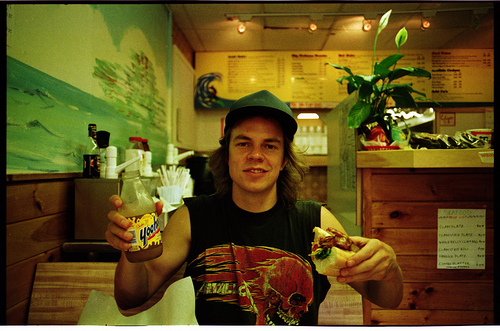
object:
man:
[104, 89, 403, 326]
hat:
[223, 89, 298, 142]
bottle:
[117, 170, 164, 263]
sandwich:
[307, 225, 362, 277]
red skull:
[263, 256, 313, 326]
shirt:
[181, 193, 331, 325]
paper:
[437, 208, 486, 269]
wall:
[361, 168, 493, 326]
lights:
[236, 14, 254, 34]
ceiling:
[172, 0, 494, 53]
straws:
[156, 163, 191, 185]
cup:
[160, 186, 184, 205]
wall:
[7, 3, 184, 184]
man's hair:
[203, 124, 312, 211]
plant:
[323, 8, 445, 147]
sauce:
[323, 246, 351, 253]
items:
[357, 116, 492, 153]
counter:
[355, 148, 493, 168]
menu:
[194, 49, 494, 110]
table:
[74, 177, 159, 240]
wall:
[180, 49, 493, 173]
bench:
[28, 261, 363, 325]